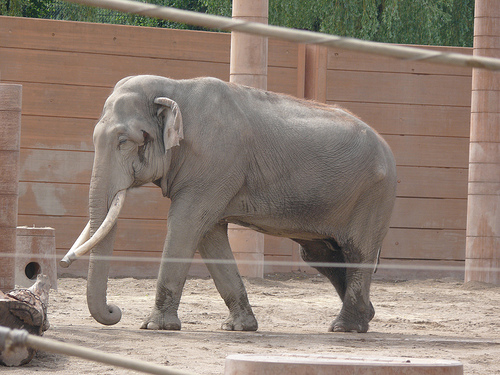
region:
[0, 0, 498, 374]
Elephant living in captivity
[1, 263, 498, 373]
Desert Sand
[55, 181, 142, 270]
Long Dull White Elephant Tusks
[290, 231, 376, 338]
Dark Spots on the Elephants Legs And Foot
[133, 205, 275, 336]
Elephants Straight Front Legs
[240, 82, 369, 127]
Line of fuzzy hair on the elephants back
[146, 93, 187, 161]
Elephant's small baby ear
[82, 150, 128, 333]
Elephant's Curled Up Trunk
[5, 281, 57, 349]
Chained wrapped around a wooden log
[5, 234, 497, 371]
Electrical wires around the elephant's den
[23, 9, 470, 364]
an elephant in a cage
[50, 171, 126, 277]
this elephant had large tusks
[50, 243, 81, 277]
this elephant has sawed off tusks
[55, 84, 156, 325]
the trunk on the elephant is long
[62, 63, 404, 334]
this elephant is gray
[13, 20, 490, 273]
a brown wooden wall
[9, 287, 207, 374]
metal objects in the cage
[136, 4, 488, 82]
a metal pole in the cage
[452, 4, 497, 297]
large support beams for the structure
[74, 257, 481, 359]
dirt on the bottom of the cage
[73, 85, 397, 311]
this is an elephant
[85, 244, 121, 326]
this is the trunk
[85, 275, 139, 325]
the trunk is coiled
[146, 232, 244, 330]
these are the legs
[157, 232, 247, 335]
the legs bare apart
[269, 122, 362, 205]
this is the belly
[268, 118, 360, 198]
the belly is fat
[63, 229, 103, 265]
these are the tusks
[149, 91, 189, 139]
this is the ear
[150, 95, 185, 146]
the ear is small in size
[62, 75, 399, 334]
A large grey elephant.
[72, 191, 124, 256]
A long white tusk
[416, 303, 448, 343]
Part of the ground.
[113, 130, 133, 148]
The elephant's eye.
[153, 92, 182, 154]
The elephant's grey ear.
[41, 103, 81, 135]
Part of the brown fence.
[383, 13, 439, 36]
Part of the green trees.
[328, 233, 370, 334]
The elephant's back leg.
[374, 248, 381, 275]
Part of the elephant's tail.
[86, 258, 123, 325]
Part of the elephant's trunk.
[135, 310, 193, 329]
left front foot on elephant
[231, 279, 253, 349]
right front foot on elephant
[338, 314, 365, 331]
left back foot on elephant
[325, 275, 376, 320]
right back foot on elephant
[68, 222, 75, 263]
white right tusk on elephant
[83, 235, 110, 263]
left tusk on elephant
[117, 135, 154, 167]
left eye on elephant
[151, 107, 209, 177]
left ear on elehant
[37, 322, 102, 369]
dirty pole on ground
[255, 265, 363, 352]
brown dirt under elephant